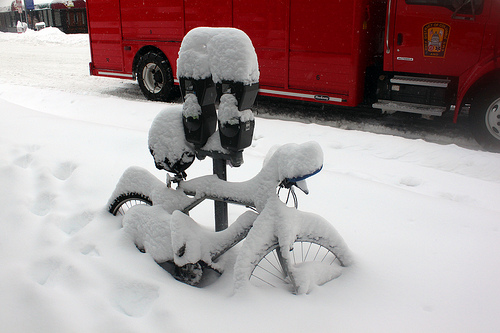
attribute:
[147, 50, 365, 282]
meter — black 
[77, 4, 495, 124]
truck — red , bright 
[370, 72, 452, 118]
steps — silver 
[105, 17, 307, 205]
meter — snow covered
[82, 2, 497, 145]
fire engine — red 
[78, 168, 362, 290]
meter — parking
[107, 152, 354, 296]
bicycle — snow-covered, leaning